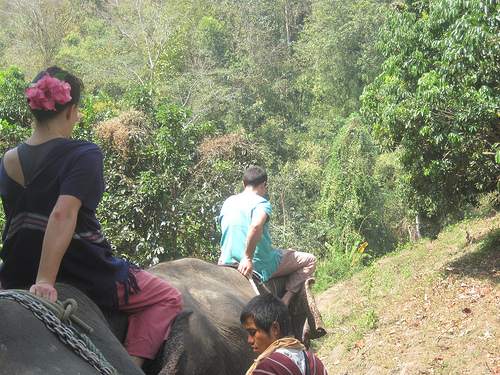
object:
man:
[240, 293, 325, 373]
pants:
[114, 261, 183, 356]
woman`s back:
[0, 136, 108, 322]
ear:
[270, 321, 280, 334]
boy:
[233, 290, 330, 373]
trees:
[1, 4, 498, 271]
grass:
[312, 221, 497, 348]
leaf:
[454, 290, 472, 302]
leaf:
[457, 277, 468, 290]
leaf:
[443, 259, 459, 277]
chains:
[3, 287, 113, 372]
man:
[217, 163, 319, 309]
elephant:
[137, 257, 327, 374]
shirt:
[205, 181, 297, 279]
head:
[28, 66, 80, 127]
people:
[3, 67, 183, 365]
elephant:
[3, 256, 150, 373]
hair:
[28, 67, 85, 122]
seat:
[223, 257, 286, 302]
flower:
[23, 73, 72, 113]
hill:
[3, 2, 500, 375]